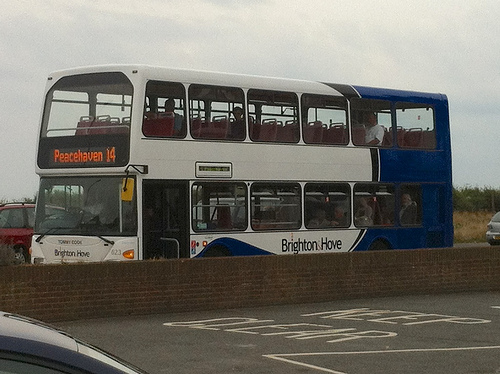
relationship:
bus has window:
[25, 59, 460, 264] [39, 73, 133, 169]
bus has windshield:
[25, 59, 460, 264] [32, 180, 139, 238]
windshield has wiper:
[32, 180, 139, 238] [34, 217, 76, 244]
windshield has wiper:
[32, 180, 139, 238] [72, 223, 115, 246]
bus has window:
[25, 59, 460, 264] [143, 79, 189, 141]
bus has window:
[25, 59, 460, 264] [187, 84, 247, 145]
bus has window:
[25, 59, 460, 264] [247, 84, 300, 147]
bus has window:
[25, 59, 460, 264] [301, 92, 350, 149]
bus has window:
[25, 59, 460, 264] [348, 97, 394, 148]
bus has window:
[25, 59, 460, 264] [395, 103, 439, 153]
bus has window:
[25, 59, 460, 264] [395, 177, 441, 228]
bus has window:
[25, 59, 460, 264] [354, 183, 399, 231]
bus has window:
[25, 59, 460, 264] [305, 182, 351, 233]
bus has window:
[25, 59, 460, 264] [249, 182, 303, 235]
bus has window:
[25, 59, 460, 264] [193, 184, 249, 230]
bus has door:
[25, 59, 460, 264] [142, 175, 192, 264]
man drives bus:
[67, 187, 113, 228] [25, 59, 460, 264]